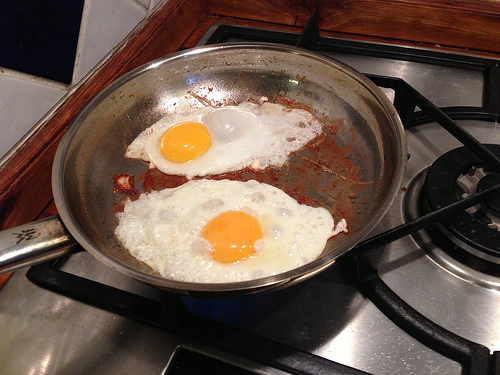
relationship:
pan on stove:
[0, 40, 406, 292] [378, 65, 495, 299]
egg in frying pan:
[123, 96, 326, 181] [90, 39, 387, 100]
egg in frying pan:
[116, 175, 349, 282] [90, 39, 387, 100]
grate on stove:
[299, 62, 485, 367] [324, 30, 463, 316]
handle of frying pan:
[3, 214, 67, 276] [15, 41, 410, 302]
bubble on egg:
[204, 106, 260, 146] [131, 97, 311, 176]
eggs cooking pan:
[53, 37, 408, 299] [0, 32, 421, 355]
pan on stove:
[1, 40, 408, 293] [6, 27, 496, 373]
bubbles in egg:
[274, 202, 291, 222] [116, 175, 349, 282]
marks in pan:
[112, 93, 365, 239] [0, 35, 407, 318]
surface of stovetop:
[293, 69, 484, 368] [56, 20, 496, 373]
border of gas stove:
[179, 2, 492, 49] [25, 22, 498, 375]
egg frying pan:
[120, 100, 310, 172] [299, 120, 406, 213]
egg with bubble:
[123, 96, 326, 181] [204, 106, 260, 146]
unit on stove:
[386, 75, 483, 256] [329, 40, 496, 270]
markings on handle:
[8, 224, 38, 246] [0, 208, 87, 273]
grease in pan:
[292, 155, 353, 200] [1, 40, 408, 293]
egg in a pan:
[123, 96, 326, 181] [98, 48, 383, 283]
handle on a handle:
[0, 214, 77, 274] [1, 214, 78, 275]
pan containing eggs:
[0, 40, 406, 292] [141, 86, 331, 195]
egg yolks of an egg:
[158, 122, 213, 164] [116, 175, 349, 282]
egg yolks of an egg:
[158, 122, 213, 164] [122, 89, 336, 175]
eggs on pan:
[114, 96, 350, 283] [1, 40, 408, 293]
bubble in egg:
[200, 109, 249, 144] [123, 96, 326, 181]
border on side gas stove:
[6, 3, 491, 231] [25, 22, 498, 375]